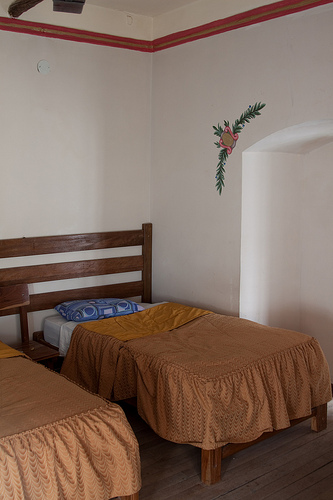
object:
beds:
[0, 221, 332, 486]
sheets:
[59, 300, 332, 451]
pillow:
[55, 297, 145, 322]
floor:
[121, 398, 332, 499]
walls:
[155, 0, 332, 348]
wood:
[6, 0, 86, 20]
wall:
[0, 1, 156, 298]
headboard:
[0, 222, 152, 318]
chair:
[0, 282, 60, 375]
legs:
[200, 391, 222, 487]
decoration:
[212, 100, 267, 196]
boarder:
[0, 1, 332, 53]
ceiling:
[91, 0, 201, 18]